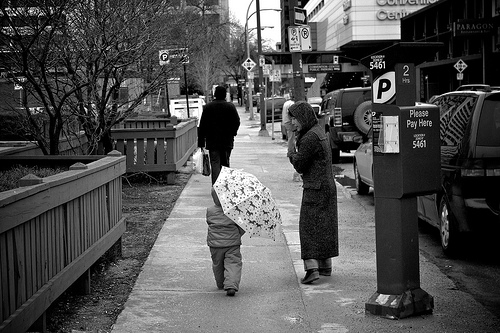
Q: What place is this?
A: It is a sidewalk.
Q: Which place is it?
A: It is a sidewalk.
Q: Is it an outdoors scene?
A: Yes, it is outdoors.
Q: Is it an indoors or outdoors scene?
A: It is outdoors.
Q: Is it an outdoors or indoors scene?
A: It is outdoors.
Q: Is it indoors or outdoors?
A: It is outdoors.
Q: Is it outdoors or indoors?
A: It is outdoors.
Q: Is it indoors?
A: No, it is outdoors.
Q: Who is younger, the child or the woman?
A: The child is younger than the woman.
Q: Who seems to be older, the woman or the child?
A: The woman is older than the child.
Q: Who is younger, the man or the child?
A: The child is younger than the man.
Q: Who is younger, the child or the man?
A: The child is younger than the man.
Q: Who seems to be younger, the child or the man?
A: The child is younger than the man.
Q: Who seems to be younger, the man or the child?
A: The child is younger than the man.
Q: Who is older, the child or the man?
A: The man is older than the child.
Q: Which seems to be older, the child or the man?
A: The man is older than the child.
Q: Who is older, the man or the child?
A: The man is older than the child.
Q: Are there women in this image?
A: Yes, there is a woman.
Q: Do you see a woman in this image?
A: Yes, there is a woman.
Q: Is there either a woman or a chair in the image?
A: Yes, there is a woman.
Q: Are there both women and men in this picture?
A: Yes, there are both a woman and a man.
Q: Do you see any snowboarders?
A: No, there are no snowboarders.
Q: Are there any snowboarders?
A: No, there are no snowboarders.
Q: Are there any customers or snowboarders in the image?
A: No, there are no snowboarders or customers.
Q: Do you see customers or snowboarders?
A: No, there are no snowboarders or customers.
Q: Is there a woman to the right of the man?
A: Yes, there is a woman to the right of the man.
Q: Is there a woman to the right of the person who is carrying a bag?
A: Yes, there is a woman to the right of the man.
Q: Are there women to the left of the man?
A: No, the woman is to the right of the man.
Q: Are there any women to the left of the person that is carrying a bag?
A: No, the woman is to the right of the man.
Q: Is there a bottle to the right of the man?
A: No, there is a woman to the right of the man.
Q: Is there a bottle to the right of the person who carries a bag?
A: No, there is a woman to the right of the man.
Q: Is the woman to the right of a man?
A: Yes, the woman is to the right of a man.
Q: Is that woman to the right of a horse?
A: No, the woman is to the right of a man.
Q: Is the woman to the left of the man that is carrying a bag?
A: No, the woman is to the right of the man.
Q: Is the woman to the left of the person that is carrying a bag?
A: No, the woman is to the right of the man.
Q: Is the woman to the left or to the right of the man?
A: The woman is to the right of the man.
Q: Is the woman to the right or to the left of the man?
A: The woman is to the right of the man.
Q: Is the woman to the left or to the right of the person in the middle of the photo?
A: The woman is to the right of the man.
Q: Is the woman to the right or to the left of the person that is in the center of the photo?
A: The woman is to the right of the man.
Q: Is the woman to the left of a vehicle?
A: Yes, the woman is to the left of a vehicle.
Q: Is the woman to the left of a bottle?
A: No, the woman is to the left of a vehicle.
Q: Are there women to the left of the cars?
A: Yes, there is a woman to the left of the cars.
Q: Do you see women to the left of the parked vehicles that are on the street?
A: Yes, there is a woman to the left of the cars.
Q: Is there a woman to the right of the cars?
A: No, the woman is to the left of the cars.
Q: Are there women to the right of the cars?
A: No, the woman is to the left of the cars.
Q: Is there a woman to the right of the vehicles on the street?
A: No, the woman is to the left of the cars.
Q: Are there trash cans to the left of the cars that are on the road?
A: No, there is a woman to the left of the cars.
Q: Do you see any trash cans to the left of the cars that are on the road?
A: No, there is a woman to the left of the cars.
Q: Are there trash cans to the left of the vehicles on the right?
A: No, there is a woman to the left of the cars.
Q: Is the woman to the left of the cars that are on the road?
A: Yes, the woman is to the left of the cars.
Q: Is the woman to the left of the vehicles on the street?
A: Yes, the woman is to the left of the cars.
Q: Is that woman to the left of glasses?
A: No, the woman is to the left of the cars.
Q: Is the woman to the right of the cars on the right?
A: No, the woman is to the left of the cars.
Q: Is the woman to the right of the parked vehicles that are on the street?
A: No, the woman is to the left of the cars.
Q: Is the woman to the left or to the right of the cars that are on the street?
A: The woman is to the left of the cars.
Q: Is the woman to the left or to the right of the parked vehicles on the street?
A: The woman is to the left of the cars.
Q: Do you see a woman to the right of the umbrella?
A: Yes, there is a woman to the right of the umbrella.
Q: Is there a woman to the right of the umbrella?
A: Yes, there is a woman to the right of the umbrella.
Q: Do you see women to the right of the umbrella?
A: Yes, there is a woman to the right of the umbrella.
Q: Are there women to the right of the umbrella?
A: Yes, there is a woman to the right of the umbrella.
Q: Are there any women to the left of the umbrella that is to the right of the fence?
A: No, the woman is to the right of the umbrella.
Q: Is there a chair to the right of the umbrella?
A: No, there is a woman to the right of the umbrella.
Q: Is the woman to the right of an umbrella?
A: Yes, the woman is to the right of an umbrella.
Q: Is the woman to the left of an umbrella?
A: No, the woman is to the right of an umbrella.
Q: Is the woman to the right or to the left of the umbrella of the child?
A: The woman is to the right of the umbrella.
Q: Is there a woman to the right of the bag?
A: Yes, there is a woman to the right of the bag.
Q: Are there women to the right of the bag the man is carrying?
A: Yes, there is a woman to the right of the bag.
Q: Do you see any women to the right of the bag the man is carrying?
A: Yes, there is a woman to the right of the bag.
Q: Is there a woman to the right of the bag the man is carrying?
A: Yes, there is a woman to the right of the bag.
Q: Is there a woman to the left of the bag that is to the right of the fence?
A: No, the woman is to the right of the bag.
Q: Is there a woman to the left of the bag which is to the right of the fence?
A: No, the woman is to the right of the bag.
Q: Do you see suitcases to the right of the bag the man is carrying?
A: No, there is a woman to the right of the bag.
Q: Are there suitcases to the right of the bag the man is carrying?
A: No, there is a woman to the right of the bag.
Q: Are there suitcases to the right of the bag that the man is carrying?
A: No, there is a woman to the right of the bag.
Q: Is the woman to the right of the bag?
A: Yes, the woman is to the right of the bag.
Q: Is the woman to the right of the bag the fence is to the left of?
A: Yes, the woman is to the right of the bag.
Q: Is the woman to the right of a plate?
A: No, the woman is to the right of the bag.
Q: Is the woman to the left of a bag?
A: No, the woman is to the right of a bag.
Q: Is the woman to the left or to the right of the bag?
A: The woman is to the right of the bag.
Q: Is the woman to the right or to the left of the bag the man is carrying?
A: The woman is to the right of the bag.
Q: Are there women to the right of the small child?
A: Yes, there is a woman to the right of the child.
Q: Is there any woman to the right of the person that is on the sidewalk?
A: Yes, there is a woman to the right of the child.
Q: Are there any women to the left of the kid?
A: No, the woman is to the right of the kid.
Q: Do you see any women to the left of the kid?
A: No, the woman is to the right of the kid.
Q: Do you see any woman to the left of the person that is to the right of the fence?
A: No, the woman is to the right of the kid.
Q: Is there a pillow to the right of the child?
A: No, there is a woman to the right of the child.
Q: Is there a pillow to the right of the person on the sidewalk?
A: No, there is a woman to the right of the child.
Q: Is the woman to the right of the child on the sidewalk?
A: Yes, the woman is to the right of the kid.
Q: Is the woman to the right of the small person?
A: Yes, the woman is to the right of the kid.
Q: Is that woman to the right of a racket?
A: No, the woman is to the right of the kid.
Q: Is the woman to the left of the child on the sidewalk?
A: No, the woman is to the right of the kid.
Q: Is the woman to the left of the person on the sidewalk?
A: No, the woman is to the right of the kid.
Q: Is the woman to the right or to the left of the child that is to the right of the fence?
A: The woman is to the right of the child.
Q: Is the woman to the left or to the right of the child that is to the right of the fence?
A: The woman is to the right of the child.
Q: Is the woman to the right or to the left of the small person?
A: The woman is to the right of the child.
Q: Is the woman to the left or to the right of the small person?
A: The woman is to the right of the child.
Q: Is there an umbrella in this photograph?
A: Yes, there is an umbrella.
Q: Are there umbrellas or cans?
A: Yes, there is an umbrella.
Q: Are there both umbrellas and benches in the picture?
A: No, there is an umbrella but no benches.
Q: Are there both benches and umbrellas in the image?
A: No, there is an umbrella but no benches.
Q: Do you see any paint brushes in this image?
A: No, there are no paint brushes.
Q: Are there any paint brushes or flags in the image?
A: No, there are no paint brushes or flags.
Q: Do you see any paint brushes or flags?
A: No, there are no paint brushes or flags.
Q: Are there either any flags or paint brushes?
A: No, there are no paint brushes or flags.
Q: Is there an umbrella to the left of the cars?
A: Yes, there is an umbrella to the left of the cars.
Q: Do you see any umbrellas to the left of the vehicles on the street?
A: Yes, there is an umbrella to the left of the cars.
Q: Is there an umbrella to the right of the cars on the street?
A: No, the umbrella is to the left of the cars.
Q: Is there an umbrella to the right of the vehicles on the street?
A: No, the umbrella is to the left of the cars.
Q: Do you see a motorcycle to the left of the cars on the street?
A: No, there is an umbrella to the left of the cars.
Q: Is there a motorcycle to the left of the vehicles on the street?
A: No, there is an umbrella to the left of the cars.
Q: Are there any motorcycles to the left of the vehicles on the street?
A: No, there is an umbrella to the left of the cars.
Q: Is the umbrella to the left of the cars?
A: Yes, the umbrella is to the left of the cars.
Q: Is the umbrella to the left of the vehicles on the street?
A: Yes, the umbrella is to the left of the cars.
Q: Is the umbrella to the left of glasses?
A: No, the umbrella is to the left of the cars.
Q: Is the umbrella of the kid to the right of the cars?
A: No, the umbrella is to the left of the cars.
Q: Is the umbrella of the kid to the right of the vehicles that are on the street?
A: No, the umbrella is to the left of the cars.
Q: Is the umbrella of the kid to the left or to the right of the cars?
A: The umbrella is to the left of the cars.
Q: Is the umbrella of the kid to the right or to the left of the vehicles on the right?
A: The umbrella is to the left of the cars.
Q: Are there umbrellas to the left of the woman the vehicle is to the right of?
A: Yes, there is an umbrella to the left of the woman.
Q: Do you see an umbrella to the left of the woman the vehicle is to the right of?
A: Yes, there is an umbrella to the left of the woman.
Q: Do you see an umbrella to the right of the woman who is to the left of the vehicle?
A: No, the umbrella is to the left of the woman.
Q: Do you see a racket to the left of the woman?
A: No, there is an umbrella to the left of the woman.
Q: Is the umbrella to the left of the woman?
A: Yes, the umbrella is to the left of the woman.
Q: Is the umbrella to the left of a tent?
A: No, the umbrella is to the left of the woman.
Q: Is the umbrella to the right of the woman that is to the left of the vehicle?
A: No, the umbrella is to the left of the woman.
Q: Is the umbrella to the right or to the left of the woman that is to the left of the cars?
A: The umbrella is to the left of the woman.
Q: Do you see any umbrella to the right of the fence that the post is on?
A: Yes, there is an umbrella to the right of the fence.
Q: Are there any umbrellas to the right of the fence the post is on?
A: Yes, there is an umbrella to the right of the fence.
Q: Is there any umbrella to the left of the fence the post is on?
A: No, the umbrella is to the right of the fence.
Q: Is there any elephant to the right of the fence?
A: No, there is an umbrella to the right of the fence.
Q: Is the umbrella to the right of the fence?
A: Yes, the umbrella is to the right of the fence.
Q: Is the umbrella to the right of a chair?
A: No, the umbrella is to the right of the fence.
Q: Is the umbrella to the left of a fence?
A: No, the umbrella is to the right of a fence.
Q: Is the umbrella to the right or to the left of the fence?
A: The umbrella is to the right of the fence.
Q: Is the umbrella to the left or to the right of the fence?
A: The umbrella is to the right of the fence.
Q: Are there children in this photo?
A: Yes, there is a child.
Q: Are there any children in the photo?
A: Yes, there is a child.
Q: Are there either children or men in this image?
A: Yes, there is a child.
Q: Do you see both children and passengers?
A: No, there is a child but no passengers.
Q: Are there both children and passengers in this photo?
A: No, there is a child but no passengers.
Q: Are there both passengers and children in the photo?
A: No, there is a child but no passengers.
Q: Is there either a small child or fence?
A: Yes, there is a small child.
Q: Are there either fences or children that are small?
A: Yes, the child is small.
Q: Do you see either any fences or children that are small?
A: Yes, the child is small.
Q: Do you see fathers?
A: No, there are no fathers.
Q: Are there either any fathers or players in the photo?
A: No, there are no fathers or players.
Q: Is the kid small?
A: Yes, the kid is small.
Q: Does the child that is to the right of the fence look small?
A: Yes, the child is small.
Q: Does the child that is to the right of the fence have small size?
A: Yes, the child is small.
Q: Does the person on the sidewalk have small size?
A: Yes, the child is small.